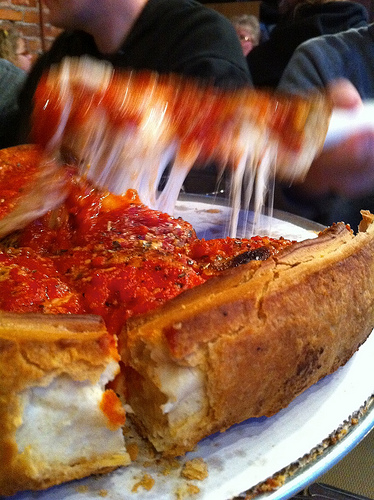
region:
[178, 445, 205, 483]
a crust of bread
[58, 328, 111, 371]
a crust of bread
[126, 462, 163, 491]
a crust of bread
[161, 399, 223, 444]
a crust of bread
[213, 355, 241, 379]
a crust of bread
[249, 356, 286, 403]
a crust of bread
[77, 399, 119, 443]
a crust of bread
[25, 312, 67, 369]
a crust of bread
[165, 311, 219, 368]
a crust of bread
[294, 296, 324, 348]
a crust of bread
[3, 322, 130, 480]
thick white cheese crust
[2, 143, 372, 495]
a deep dish pizza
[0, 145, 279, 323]
red sauce on pizza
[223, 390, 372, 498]
trimming on the plate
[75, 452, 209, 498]
crumbs on the plate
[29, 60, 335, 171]
a slice in the air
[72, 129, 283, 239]
the cheesy strings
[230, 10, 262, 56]
a grey haired lady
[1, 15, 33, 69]
a lady wearing glasses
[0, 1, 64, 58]
brick wall restaurant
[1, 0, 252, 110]
man in black sweater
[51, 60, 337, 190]
cheese hanging from pizza slice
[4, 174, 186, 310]
tomato sauce on pizza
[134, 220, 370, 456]
thick crust of pizza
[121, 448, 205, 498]
crumbs on white plate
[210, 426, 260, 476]
grease stains on plate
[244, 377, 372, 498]
edge of pizza plate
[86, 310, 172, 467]
cut between pizza slices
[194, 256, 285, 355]
crack in pizza crust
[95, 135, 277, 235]
stretced strings of cheese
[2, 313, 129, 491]
the cheese in a crust of a pizza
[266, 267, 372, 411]
the crust of a pizza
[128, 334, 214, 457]
cheese in a crust of a pizza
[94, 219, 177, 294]
the toppings on a pizza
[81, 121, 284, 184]
the melted cheese of a pizza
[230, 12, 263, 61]
the head of a person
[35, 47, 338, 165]
a slice of pizza being removed from a pizza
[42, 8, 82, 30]
the chin of a person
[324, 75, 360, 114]
a blurry thumb of a hand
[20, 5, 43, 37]
the bricks of a wall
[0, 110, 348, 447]
Pizza on a plate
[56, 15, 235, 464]
The pizza is deep dish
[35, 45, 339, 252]
One piece of pizza being lifted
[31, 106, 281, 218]
The cheese is melty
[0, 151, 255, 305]
Red sauce on the pizza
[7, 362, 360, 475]
Cardboard just under the pizza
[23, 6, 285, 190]
A man in a black shirt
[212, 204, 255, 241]
Shadow under the pizza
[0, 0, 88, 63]
the wall is brick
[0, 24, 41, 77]
A woman with glasses in the background